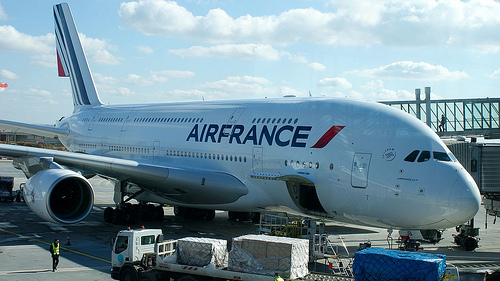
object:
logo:
[185, 123, 347, 148]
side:
[55, 95, 479, 230]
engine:
[21, 168, 94, 227]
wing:
[0, 143, 277, 213]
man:
[50, 239, 62, 272]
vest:
[50, 242, 60, 256]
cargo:
[175, 233, 447, 281]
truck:
[109, 225, 500, 281]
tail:
[53, 2, 104, 153]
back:
[54, 110, 95, 154]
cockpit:
[401, 149, 457, 164]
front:
[376, 115, 481, 230]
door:
[351, 151, 372, 189]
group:
[77, 116, 299, 163]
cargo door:
[278, 174, 335, 221]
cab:
[113, 228, 161, 281]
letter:
[185, 123, 197, 142]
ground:
[0, 155, 500, 280]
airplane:
[1, 2, 481, 251]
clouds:
[2, 0, 499, 109]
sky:
[0, 0, 500, 108]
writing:
[185, 123, 313, 147]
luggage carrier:
[352, 247, 446, 280]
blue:
[351, 247, 445, 281]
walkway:
[312, 233, 355, 278]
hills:
[0, 113, 61, 129]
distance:
[0, 0, 500, 155]